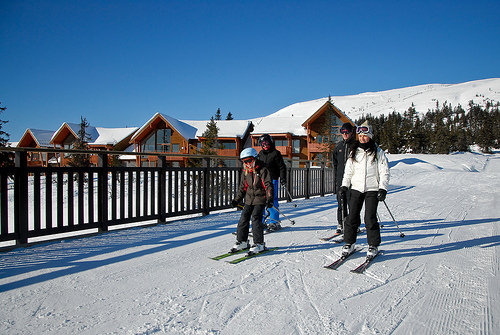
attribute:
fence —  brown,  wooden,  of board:
[76, 124, 247, 245]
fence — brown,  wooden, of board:
[0, 145, 335, 249]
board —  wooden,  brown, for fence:
[201, 240, 236, 267]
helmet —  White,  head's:
[238, 145, 259, 160]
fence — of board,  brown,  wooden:
[16, 144, 223, 211]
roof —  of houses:
[212, 75, 414, 266]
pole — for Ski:
[378, 192, 407, 238]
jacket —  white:
[333, 143, 392, 193]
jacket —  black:
[258, 150, 283, 169]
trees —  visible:
[465, 110, 482, 142]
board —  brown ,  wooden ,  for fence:
[316, 219, 400, 275]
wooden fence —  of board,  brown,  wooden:
[0, 146, 335, 252]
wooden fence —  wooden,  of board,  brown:
[88, 165, 115, 233]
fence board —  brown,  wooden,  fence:
[77, 167, 85, 223]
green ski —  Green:
[211, 245, 249, 260]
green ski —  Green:
[226, 248, 272, 264]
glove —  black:
[376, 188, 386, 199]